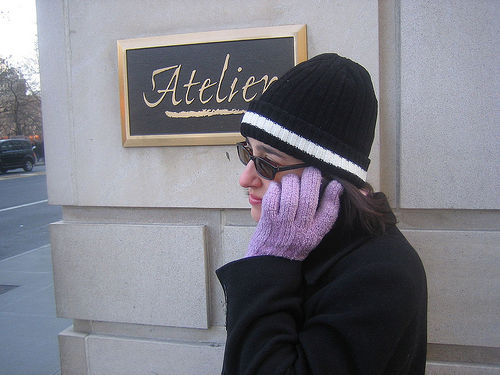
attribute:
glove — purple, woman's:
[242, 161, 347, 264]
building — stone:
[37, 3, 499, 372]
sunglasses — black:
[235, 139, 312, 180]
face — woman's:
[178, 64, 447, 339]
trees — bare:
[2, 53, 44, 135]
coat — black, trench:
[212, 177, 433, 369]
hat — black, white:
[237, 50, 382, 187]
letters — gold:
[141, 52, 278, 108]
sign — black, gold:
[109, 18, 314, 158]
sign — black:
[124, 23, 345, 151]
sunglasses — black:
[237, 142, 297, 183]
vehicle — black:
[7, 136, 36, 171]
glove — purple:
[245, 166, 342, 254]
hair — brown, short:
[317, 179, 389, 239]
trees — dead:
[3, 64, 39, 144]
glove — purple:
[250, 162, 344, 258]